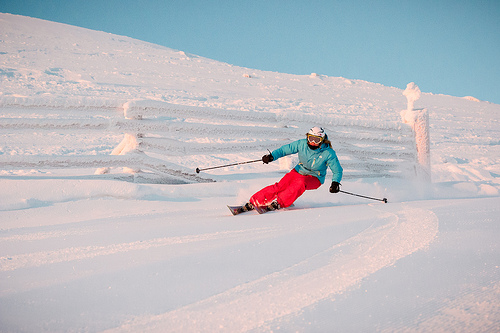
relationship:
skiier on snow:
[228, 124, 343, 218] [0, 13, 498, 332]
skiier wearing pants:
[228, 124, 343, 218] [247, 169, 322, 211]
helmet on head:
[307, 126, 327, 140] [305, 124, 327, 150]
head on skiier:
[305, 124, 327, 150] [228, 124, 343, 218]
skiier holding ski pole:
[228, 124, 343, 218] [333, 187, 390, 204]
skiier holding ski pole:
[228, 124, 343, 218] [195, 156, 264, 173]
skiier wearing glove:
[228, 124, 343, 218] [328, 182, 341, 194]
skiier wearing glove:
[228, 124, 343, 218] [261, 151, 272, 164]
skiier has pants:
[228, 124, 343, 218] [247, 169, 322, 211]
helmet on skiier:
[307, 126, 327, 140] [228, 124, 343, 218]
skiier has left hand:
[228, 124, 343, 218] [327, 181, 341, 194]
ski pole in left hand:
[333, 187, 390, 204] [327, 181, 341, 194]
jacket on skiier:
[262, 135, 346, 188] [228, 124, 343, 218]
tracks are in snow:
[3, 95, 425, 180] [0, 13, 498, 332]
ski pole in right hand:
[195, 156, 264, 173] [262, 151, 274, 168]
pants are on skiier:
[247, 169, 322, 211] [228, 124, 343, 218]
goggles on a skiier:
[306, 135, 323, 144] [228, 124, 343, 218]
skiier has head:
[228, 124, 343, 218] [305, 124, 327, 150]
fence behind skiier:
[1, 78, 440, 197] [228, 124, 343, 218]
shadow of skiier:
[262, 198, 363, 210] [228, 124, 343, 218]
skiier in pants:
[228, 124, 343, 218] [247, 169, 322, 211]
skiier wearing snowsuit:
[228, 124, 343, 218] [246, 137, 342, 208]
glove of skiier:
[328, 182, 341, 194] [228, 124, 343, 218]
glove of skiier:
[261, 151, 272, 164] [228, 124, 343, 218]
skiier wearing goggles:
[228, 124, 343, 218] [306, 135, 323, 144]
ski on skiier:
[257, 203, 295, 215] [228, 124, 343, 218]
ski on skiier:
[225, 199, 256, 217] [228, 124, 343, 218]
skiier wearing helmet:
[228, 124, 343, 218] [307, 126, 327, 140]